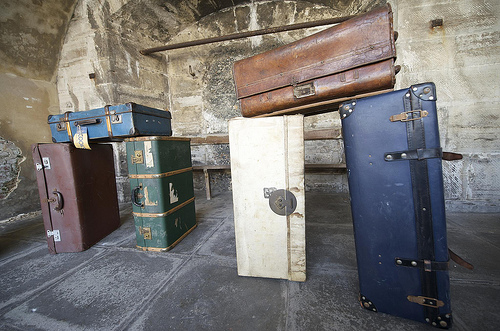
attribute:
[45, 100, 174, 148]
suitcase — above, blue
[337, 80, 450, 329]
suitcase — old, blue, closed, dark blue, big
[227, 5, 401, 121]
suitcase — old, above, closed, brown, leather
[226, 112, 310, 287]
suitcase — old, closed, white, upright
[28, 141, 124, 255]
suitcase — old, closed, brown, red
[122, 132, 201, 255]
suitcase — old, closed, green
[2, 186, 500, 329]
floor — cement, cemented, grey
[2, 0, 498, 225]
wall — rusty, stone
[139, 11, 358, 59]
bar — metal, stick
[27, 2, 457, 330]
suitcases — several, displayed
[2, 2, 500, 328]
cave — cement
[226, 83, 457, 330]
luggage — white, blue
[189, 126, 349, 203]
bench — wooden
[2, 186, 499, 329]
panels — rectangular, gray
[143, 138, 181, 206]
labels — damaged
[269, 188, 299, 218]
latch — circular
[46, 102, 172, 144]
suitcase — blue, closed